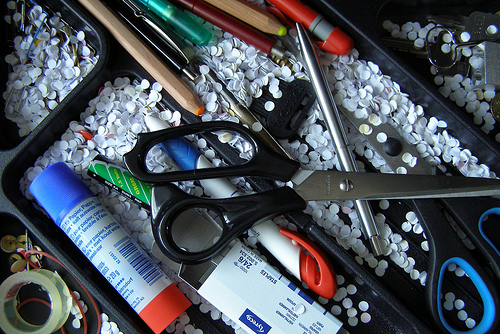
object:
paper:
[387, 86, 405, 98]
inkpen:
[140, 109, 336, 297]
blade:
[343, 165, 498, 207]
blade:
[343, 98, 416, 163]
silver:
[356, 175, 442, 187]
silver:
[368, 120, 416, 162]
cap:
[29, 161, 100, 229]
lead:
[276, 27, 286, 34]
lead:
[193, 105, 205, 114]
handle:
[147, 178, 303, 263]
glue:
[26, 159, 192, 332]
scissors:
[340, 104, 500, 334]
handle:
[123, 122, 301, 187]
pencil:
[77, 0, 209, 117]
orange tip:
[193, 103, 206, 118]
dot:
[373, 130, 388, 143]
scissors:
[121, 121, 499, 256]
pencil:
[185, 0, 286, 37]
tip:
[271, 22, 291, 38]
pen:
[289, 19, 386, 264]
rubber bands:
[0, 267, 73, 334]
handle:
[426, 235, 497, 334]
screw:
[335, 174, 353, 191]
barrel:
[232, 214, 305, 279]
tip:
[195, 104, 205, 118]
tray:
[1, 3, 498, 328]